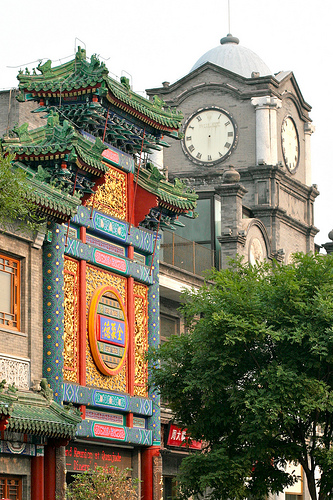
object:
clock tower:
[143, 0, 319, 277]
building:
[146, 0, 320, 497]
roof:
[1, 41, 199, 153]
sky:
[0, 1, 332, 256]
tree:
[141, 241, 333, 499]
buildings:
[0, 38, 200, 498]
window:
[0, 252, 23, 330]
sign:
[86, 281, 131, 377]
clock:
[277, 110, 301, 175]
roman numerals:
[183, 134, 192, 146]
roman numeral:
[215, 112, 223, 119]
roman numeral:
[221, 121, 232, 127]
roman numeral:
[226, 129, 234, 139]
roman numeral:
[222, 140, 233, 149]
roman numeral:
[217, 148, 224, 158]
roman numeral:
[204, 151, 213, 160]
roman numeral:
[195, 151, 202, 159]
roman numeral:
[187, 144, 197, 157]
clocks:
[178, 101, 242, 175]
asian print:
[167, 425, 206, 448]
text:
[64, 444, 124, 471]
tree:
[64, 456, 137, 499]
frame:
[0, 255, 21, 333]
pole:
[226, 1, 232, 38]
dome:
[188, 34, 274, 79]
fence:
[161, 229, 216, 278]